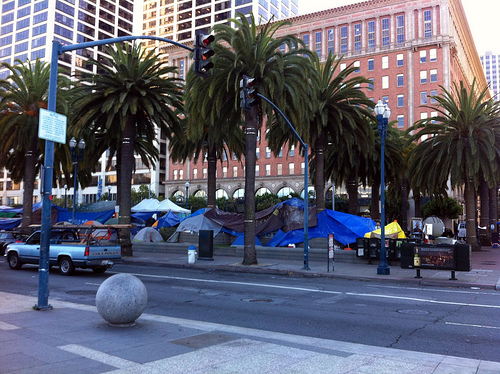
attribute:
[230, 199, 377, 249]
tarp — blue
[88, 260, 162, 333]
ball — CONCRETE, BIG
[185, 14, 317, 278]
palm tree — GREEN, LARGE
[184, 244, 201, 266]
fire hydrant — BLUE, WHITE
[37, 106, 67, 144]
sign — WHITE, GREEN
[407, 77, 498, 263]
tree — LARGE, GREEN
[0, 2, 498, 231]
buildings — TALL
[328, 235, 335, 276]
sign — WHITE, RED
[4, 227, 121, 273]
truck — LIGHT BLUE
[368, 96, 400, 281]
streetlight — OLD-FASHION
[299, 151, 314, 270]
pole — blue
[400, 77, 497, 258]
palm tree — GREEN, LARGE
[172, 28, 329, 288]
palm tree — LARGE, GREEN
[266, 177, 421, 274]
tarp — blue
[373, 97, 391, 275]
street light — BLUE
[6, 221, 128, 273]
truck — PICK UP, LIGHT BLUE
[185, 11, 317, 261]
tree — BROWN, LONG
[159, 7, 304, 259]
tree — GREEN, LARGE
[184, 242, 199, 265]
fire hydrant — WHITE, BLUE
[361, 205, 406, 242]
tarp — YELLOW, BRIGHT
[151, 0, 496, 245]
building — GREY, RED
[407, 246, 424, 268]
bottle — GREEN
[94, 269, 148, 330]
object — ROUND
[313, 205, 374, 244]
tarp — blue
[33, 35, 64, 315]
pole — blue